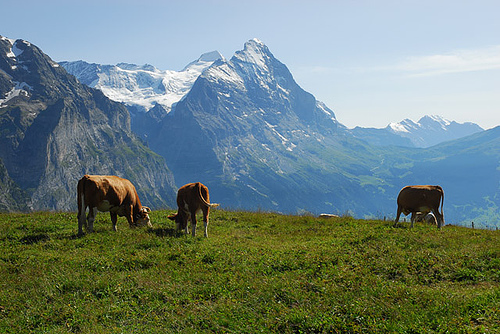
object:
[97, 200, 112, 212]
udder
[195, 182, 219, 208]
tail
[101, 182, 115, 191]
fur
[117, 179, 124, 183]
brown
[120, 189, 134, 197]
color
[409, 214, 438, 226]
cows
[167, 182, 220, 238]
cows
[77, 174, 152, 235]
cows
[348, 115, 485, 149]
mountain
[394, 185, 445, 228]
cattle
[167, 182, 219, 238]
cattle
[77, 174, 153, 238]
cattle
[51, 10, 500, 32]
sky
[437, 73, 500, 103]
clouds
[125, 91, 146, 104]
snow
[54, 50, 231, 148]
mountain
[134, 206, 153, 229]
face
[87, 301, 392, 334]
grass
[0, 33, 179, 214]
hill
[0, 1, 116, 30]
clouds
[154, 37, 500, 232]
peak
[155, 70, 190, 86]
snow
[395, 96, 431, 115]
cloud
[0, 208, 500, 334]
ground